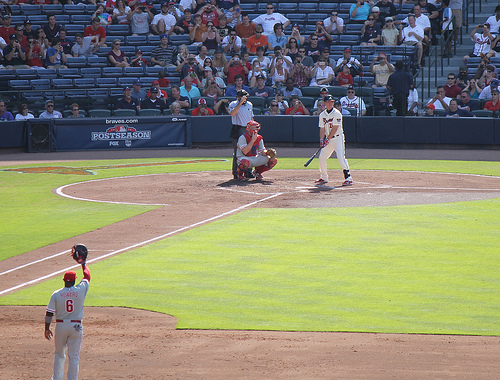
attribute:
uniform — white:
[315, 110, 355, 181]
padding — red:
[236, 132, 277, 179]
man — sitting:
[158, 74, 193, 116]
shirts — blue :
[122, 89, 164, 109]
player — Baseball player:
[304, 90, 356, 188]